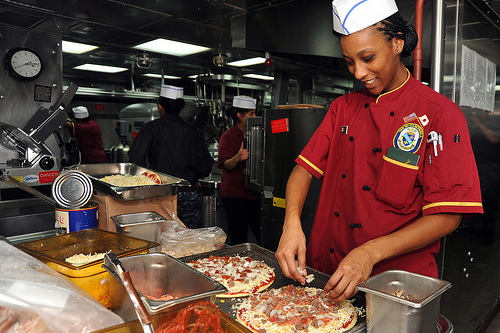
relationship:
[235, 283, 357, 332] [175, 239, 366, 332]
pizza on tray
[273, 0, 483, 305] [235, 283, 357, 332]
woman making pizza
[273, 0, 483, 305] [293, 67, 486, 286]
woman wearing shirt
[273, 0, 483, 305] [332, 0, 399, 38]
woman wearing hat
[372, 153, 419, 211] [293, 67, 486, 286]
pocket on shirt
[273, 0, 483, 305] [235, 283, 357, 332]
woman preparing pizza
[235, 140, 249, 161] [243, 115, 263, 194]
hand on oven door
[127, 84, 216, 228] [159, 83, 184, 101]
person wearing hat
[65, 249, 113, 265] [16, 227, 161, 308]
cheese in container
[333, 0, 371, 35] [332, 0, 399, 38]
stripe on hat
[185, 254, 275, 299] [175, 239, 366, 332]
pizza on tray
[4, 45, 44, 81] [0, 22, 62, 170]
clock hanging on wall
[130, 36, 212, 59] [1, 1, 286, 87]
light in ceiling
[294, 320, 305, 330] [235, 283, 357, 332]
sausage on pizza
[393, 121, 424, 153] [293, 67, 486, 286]
patch on shirt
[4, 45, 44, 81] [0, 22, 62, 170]
clock on wall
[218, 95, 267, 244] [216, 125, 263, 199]
person wearing uniform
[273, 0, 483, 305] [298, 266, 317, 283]
woman putting cheese